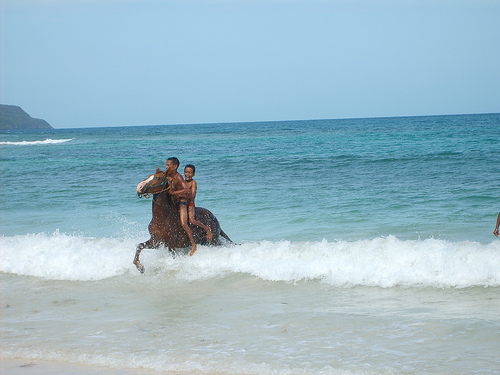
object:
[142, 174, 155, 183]
spot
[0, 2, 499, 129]
sky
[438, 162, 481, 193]
ground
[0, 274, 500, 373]
beach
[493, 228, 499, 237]
hand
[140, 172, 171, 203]
bridle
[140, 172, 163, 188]
face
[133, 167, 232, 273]
brown horse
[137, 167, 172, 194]
head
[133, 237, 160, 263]
leg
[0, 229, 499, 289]
surf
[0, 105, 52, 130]
cliff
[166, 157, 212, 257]
boys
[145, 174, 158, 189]
fur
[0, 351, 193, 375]
sand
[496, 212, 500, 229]
arm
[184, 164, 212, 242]
boy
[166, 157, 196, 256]
boy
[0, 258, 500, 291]
line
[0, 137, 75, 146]
foam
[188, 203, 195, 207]
suit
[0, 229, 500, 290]
foam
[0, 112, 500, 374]
ocean